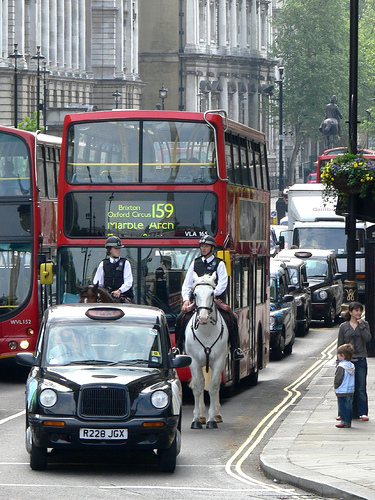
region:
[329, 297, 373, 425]
the people on the sidewalk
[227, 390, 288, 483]
the lines painted on the street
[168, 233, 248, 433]
the man on the white horse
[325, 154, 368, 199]
yellow flowers on the street pole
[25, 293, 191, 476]
the taxi in the street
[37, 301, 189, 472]
the taxi is black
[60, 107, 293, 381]
the double decker bus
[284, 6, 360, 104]
the trees with green leaves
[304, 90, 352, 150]
the statue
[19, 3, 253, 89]
the old buildings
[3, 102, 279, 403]
two buses driving next to each other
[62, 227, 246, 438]
two people riding horses in the street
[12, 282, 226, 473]
a small compact car in front of the horses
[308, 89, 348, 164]
statue of a man riding a horse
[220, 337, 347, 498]
two yellow squiggly lines on the road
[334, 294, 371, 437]
a woman and child standing on a sidewalk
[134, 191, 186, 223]
bus number 159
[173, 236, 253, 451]
man riding a white horse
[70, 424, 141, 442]
white license plate with black letters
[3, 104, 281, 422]
two red double decker buses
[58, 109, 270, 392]
a double decker red bus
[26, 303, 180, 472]
a black car in street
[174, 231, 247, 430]
police officer on horse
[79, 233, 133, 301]
police officer on horse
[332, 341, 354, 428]
little boy standing on sidewalk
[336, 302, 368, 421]
a woman standing on sidewalk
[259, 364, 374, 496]
a paved city sidewalk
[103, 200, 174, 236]
electronic bus destination sign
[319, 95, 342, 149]
statue of man on horse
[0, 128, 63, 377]
double decker red bus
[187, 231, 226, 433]
mand on white horse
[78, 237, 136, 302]
woman on brown horse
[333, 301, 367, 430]
little boy standing beside woman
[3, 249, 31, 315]
window on the red bus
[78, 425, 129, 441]
license plate on the black car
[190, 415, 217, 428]
black hoofs on the horse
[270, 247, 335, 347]
three cars in a row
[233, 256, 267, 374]
doors on the red bus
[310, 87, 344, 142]
statue of a man on a horse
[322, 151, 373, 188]
flowers hanging from pole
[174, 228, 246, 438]
Rider on white horse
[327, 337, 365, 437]
Little boy in Light Blue jacket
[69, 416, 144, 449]
License plate numbered R228 JGX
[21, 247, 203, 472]
Black Taxi cab at front of traffic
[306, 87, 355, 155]
Statue of horseback rider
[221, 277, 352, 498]
Wavy double line on road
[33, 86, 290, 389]
Red double-decker bus numbered 159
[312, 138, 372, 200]
Plant with yellow and purple flowers hanging from pole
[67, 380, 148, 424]
Grill on front of black car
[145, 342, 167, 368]
Yellow registration sticker on car